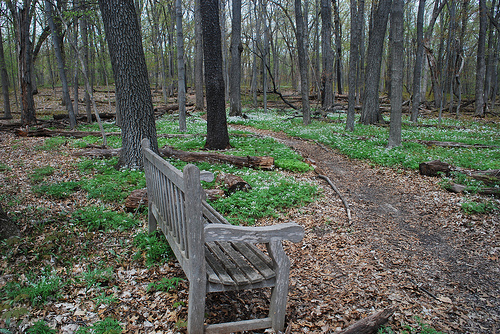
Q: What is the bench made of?
A: Wood.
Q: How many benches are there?
A: 1.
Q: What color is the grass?
A: Green.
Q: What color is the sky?
A: Blue.